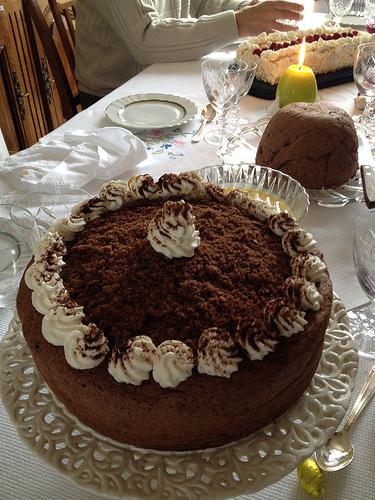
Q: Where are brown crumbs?
A: On top of cake.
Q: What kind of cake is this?
A: Chocolate.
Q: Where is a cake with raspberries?
A: Behind the candle.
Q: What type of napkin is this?
A: Linen.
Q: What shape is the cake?
A: Round.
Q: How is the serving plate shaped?
A: Round.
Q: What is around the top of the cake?
A: Decorative icing.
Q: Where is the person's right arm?
A: On the table.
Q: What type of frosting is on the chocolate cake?
A: Vanilla.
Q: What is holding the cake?
A: A decorative plate.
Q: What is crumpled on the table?
A: A napkin.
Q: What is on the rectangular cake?
A: Raspberries.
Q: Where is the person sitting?
A: At the table.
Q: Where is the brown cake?
A: On the table.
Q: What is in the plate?
A: A cake.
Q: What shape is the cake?
A: Round.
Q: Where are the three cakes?
A: On the table.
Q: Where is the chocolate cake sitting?
A: Cake stand.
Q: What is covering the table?
A: Tablecloth.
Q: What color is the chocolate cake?
A: Brown.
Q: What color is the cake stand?
A: White.